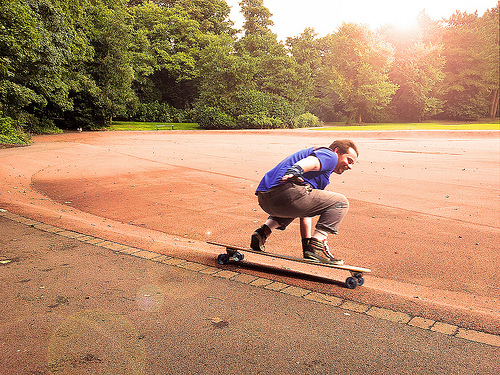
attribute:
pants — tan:
[257, 175, 355, 236]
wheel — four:
[215, 253, 231, 265]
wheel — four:
[232, 250, 244, 262]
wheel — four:
[344, 275, 357, 289]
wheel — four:
[355, 275, 366, 287]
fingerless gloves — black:
[279, 162, 307, 188]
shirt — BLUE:
[259, 148, 337, 190]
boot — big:
[305, 235, 350, 267]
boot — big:
[248, 221, 271, 251]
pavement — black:
[20, 269, 247, 356]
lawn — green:
[110, 122, 499, 131]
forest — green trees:
[1, 0, 498, 145]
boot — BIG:
[301, 233, 348, 268]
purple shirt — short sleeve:
[243, 124, 345, 219]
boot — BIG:
[297, 228, 352, 280]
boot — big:
[245, 226, 357, 263]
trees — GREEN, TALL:
[76, 22, 222, 144]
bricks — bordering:
[0, 207, 498, 347]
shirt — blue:
[260, 147, 352, 200]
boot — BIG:
[300, 235, 343, 257]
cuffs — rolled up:
[256, 213, 341, 234]